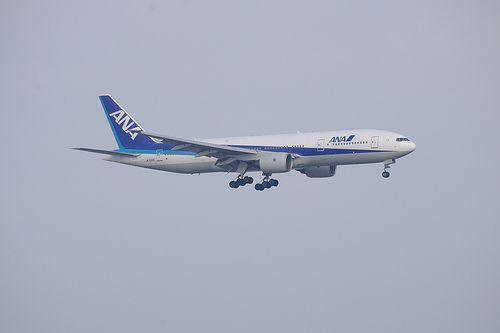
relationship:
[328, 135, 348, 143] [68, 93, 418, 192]
"ana" on side of a plane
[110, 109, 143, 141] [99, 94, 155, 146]
word on side of tail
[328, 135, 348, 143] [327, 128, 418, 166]
"ana" on front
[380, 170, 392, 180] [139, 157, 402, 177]
landing gear coming from bottom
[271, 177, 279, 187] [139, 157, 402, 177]
wheel coming from bottom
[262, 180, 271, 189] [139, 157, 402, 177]
wheel coming from bottom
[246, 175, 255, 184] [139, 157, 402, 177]
wheel coming from bottom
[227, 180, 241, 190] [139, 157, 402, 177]
landing wheels coming from bottom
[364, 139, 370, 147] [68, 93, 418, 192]
window on side of plane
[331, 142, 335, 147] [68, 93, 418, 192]
window on side of plane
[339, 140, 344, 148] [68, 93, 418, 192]
window on side of plane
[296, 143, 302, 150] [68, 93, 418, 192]
window on side of plane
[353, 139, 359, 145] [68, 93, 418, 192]
window on side of plane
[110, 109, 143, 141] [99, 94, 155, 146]
word on part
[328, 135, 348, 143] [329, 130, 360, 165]
word on part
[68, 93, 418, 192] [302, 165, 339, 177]
plane has an engine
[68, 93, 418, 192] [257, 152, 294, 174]
plane has an engine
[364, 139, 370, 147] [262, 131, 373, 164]
small window down side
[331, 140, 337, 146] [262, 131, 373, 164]
small window down side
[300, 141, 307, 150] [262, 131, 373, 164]
small window down side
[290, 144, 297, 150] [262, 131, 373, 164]
small window down side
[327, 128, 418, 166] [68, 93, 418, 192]
front of plane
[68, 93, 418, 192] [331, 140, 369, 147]
plane has a row of black windows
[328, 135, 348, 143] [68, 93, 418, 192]
"ana" logo on side of plane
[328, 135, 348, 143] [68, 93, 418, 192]
ana logo on side of plane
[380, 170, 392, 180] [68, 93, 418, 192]
landing gear on side of plane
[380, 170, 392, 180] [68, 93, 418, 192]
landing gear on plane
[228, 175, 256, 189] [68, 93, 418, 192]
landing wheels on plane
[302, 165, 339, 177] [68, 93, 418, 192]
engine on side of a plane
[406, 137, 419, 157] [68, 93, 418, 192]
nose on front of plane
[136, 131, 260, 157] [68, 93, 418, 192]
wing on side of plane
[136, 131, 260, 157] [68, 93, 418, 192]
wing on back of a plane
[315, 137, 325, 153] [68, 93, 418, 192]
door on side of plane